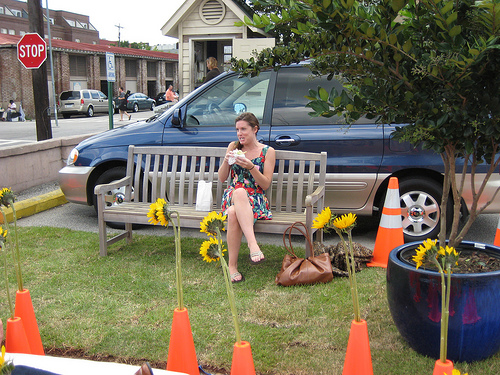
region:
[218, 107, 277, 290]
woman sitting on a bench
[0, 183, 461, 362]
row of sunflowers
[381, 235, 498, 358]
large blue colored flower pot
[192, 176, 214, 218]
white bag on the side of the woman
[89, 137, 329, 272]
wooden bench on a lawn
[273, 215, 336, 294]
woman's brown leather bag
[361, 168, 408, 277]
orange and white traffic cone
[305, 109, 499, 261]
small tree growing in a blue pot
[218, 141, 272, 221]
colorful sundress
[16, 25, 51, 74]
red and white stop sign on a wooden pole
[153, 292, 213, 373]
The cone is orange.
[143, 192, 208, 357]
The flowers are sunflowers.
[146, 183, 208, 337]
Flowers are coming out of the cone.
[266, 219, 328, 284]
The purse is brown.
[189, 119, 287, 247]
Her dress is flowered.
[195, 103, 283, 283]
She is sitting.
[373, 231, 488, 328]
The pot is blue.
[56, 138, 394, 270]
The bench is grey.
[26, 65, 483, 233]
The car is parked.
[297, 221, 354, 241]
The flowers are yellow.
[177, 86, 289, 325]
woman sitting on a bench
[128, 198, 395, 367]
orange cones holding flowers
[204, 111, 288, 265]
woman in a colorful dress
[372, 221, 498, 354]
big dark blue vase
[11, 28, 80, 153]
red and white stop sign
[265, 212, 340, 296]
leathery light brown purse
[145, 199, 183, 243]
large petaled yellow flower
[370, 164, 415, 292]
big orange and white cone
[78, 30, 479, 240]
blue and silver van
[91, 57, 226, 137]
people walking on the sidewalk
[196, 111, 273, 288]
A white bag next to a woman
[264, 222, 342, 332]
Brown purse on grass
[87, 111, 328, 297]
Woman sitting on a wooden bench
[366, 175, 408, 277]
Orange and white cone.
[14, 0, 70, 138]
Stop sign on a wooden post.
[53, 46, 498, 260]
Blue van behind woman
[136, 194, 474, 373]
Sunflowers in orange cones.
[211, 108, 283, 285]
Woman wearing a floral dress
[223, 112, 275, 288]
woman wearing slippers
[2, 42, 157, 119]
parallel parked cars next to a brick building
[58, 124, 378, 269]
woman sitting on a wooden bench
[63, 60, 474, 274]
blue minivan behind woman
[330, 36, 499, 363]
blue planter with tree in it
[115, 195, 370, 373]
sunflowers inside of traffic cones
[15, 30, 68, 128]
stop sign in front of van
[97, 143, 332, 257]
bench is made of wooden slats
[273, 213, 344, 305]
purse sitting on the grass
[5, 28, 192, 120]
buildings behind the woman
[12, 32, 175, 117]
cars parked along the street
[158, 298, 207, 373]
traffic cones are orange